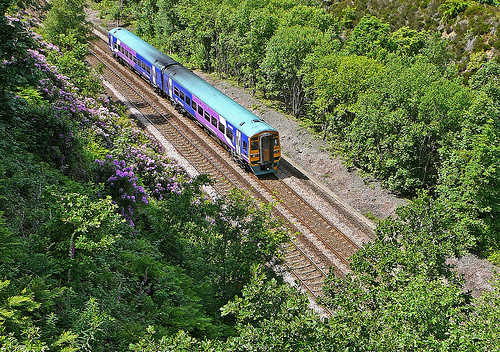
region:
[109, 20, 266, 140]
light blue top of the train cars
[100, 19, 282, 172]
train with two cars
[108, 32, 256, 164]
purple sides of the train cars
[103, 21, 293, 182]
train traveling down the tracks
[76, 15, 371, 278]
track the train is traveling on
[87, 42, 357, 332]
unused train tracks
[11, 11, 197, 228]
purple flowers growing beside the train tracks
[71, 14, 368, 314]
two sets of train tracks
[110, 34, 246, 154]
windows along the train cars sides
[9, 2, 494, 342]
trees lining the train tracks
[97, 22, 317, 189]
a colorful train on tracks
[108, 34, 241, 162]
two shades of purple on side of train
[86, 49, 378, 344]
an empty track next to train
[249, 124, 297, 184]
a yellow front of the train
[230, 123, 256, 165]
white doors on the train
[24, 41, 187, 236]
pink flowers on the hillside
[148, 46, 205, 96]
black marks on top of train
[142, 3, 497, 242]
trees along side of the train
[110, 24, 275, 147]
light blue on top of train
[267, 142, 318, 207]
shadow cast by train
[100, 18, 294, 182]
A turquoise train passing through a dense wooded area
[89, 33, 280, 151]
passenger train going through wilderness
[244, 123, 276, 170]
yellow front of train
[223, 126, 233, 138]
glass window on side of train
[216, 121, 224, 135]
glass window on side of train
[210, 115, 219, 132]
glass window on side of train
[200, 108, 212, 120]
glass window on side of train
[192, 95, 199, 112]
glass window on side of train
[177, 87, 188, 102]
glass window on side of train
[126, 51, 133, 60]
glass window on side of train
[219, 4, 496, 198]
trees growing on right of track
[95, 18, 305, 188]
train on the tracks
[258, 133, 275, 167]
door on the front of the train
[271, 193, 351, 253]
tracks on the ground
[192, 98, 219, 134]
purple around the windows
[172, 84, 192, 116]
blue around the windows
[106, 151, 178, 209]
purple flowers on the bush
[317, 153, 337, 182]
dirt on the side of the tracks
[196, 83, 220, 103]
light blue on top of the train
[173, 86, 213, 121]
windows on the train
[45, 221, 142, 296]
bunch of trees in the woods